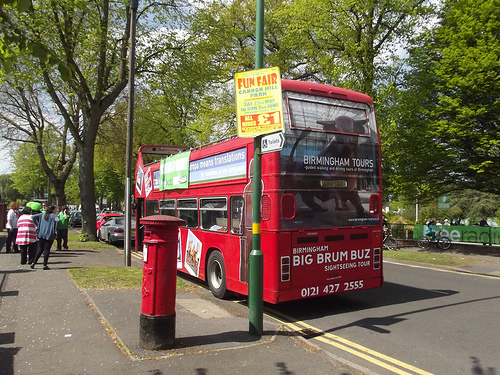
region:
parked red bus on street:
[125, 78, 388, 305]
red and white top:
[10, 210, 40, 245]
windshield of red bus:
[292, 165, 382, 220]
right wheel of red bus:
[200, 245, 230, 295]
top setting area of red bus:
[271, 70, 386, 160]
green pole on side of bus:
[245, 47, 265, 342]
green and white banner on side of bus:
[155, 145, 190, 190]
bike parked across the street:
[421, 221, 452, 243]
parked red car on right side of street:
[95, 210, 116, 235]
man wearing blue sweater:
[34, 215, 59, 245]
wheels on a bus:
[202, 248, 226, 297]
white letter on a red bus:
[291, 247, 356, 267]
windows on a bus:
[186, 192, 228, 236]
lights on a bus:
[278, 254, 295, 286]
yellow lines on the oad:
[302, 321, 345, 346]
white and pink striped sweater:
[12, 210, 39, 250]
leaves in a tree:
[421, 115, 462, 150]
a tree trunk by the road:
[78, 172, 106, 244]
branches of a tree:
[16, 115, 43, 143]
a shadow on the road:
[349, 300, 420, 337]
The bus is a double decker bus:
[121, 133, 390, 305]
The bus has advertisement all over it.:
[153, 156, 238, 188]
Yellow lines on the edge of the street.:
[299, 322, 394, 373]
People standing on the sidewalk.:
[8, 188, 75, 259]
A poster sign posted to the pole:
[226, 55, 278, 135]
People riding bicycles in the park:
[381, 221, 497, 244]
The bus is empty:
[157, 131, 280, 155]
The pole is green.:
[238, 11, 265, 363]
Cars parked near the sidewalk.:
[92, 200, 142, 240]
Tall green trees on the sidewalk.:
[23, 23, 121, 262]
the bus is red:
[134, 77, 385, 299]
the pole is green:
[243, 139, 260, 340]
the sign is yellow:
[235, 64, 282, 140]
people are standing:
[2, 200, 71, 266]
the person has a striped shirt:
[13, 213, 35, 245]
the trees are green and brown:
[4, 1, 499, 241]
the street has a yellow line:
[242, 295, 434, 373]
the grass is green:
[66, 264, 145, 291]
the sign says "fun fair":
[232, 65, 281, 140]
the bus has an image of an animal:
[278, 118, 370, 220]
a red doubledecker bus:
[110, 66, 409, 315]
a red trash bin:
[104, 197, 204, 354]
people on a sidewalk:
[3, 179, 103, 333]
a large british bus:
[101, 67, 408, 317]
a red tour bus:
[114, 62, 415, 317]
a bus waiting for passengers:
[111, 65, 412, 340]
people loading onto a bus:
[8, 66, 438, 351]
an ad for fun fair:
[222, 45, 300, 152]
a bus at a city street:
[6, 2, 493, 368]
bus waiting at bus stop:
[6, 6, 471, 373]